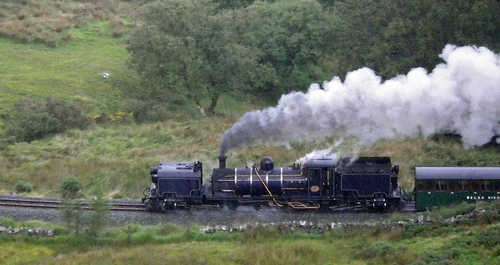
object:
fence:
[2, 210, 492, 237]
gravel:
[2, 213, 278, 229]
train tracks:
[0, 193, 141, 213]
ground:
[285, 232, 404, 259]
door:
[308, 166, 323, 196]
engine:
[212, 147, 402, 210]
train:
[147, 156, 500, 212]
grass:
[12, 235, 462, 263]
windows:
[418, 181, 499, 189]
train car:
[414, 164, 500, 212]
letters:
[468, 196, 498, 201]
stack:
[217, 155, 227, 170]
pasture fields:
[12, 139, 140, 189]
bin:
[338, 156, 402, 201]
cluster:
[84, 107, 137, 126]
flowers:
[88, 106, 135, 123]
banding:
[231, 168, 307, 189]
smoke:
[215, 44, 496, 157]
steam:
[214, 44, 497, 172]